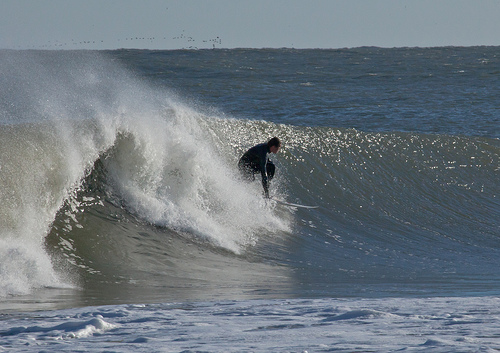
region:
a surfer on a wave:
[224, 122, 289, 205]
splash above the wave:
[5, 37, 213, 183]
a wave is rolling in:
[8, 50, 476, 285]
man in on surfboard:
[230, 125, 319, 217]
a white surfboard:
[256, 189, 320, 213]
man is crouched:
[240, 134, 287, 204]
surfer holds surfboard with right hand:
[222, 120, 325, 225]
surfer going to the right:
[230, 125, 318, 230]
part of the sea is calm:
[159, 42, 488, 117]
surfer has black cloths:
[211, 120, 301, 205]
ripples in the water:
[40, 303, 124, 350]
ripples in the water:
[63, 129, 152, 211]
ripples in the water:
[145, 171, 277, 308]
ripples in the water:
[319, 121, 386, 173]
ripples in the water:
[399, 116, 474, 160]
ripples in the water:
[362, 204, 424, 259]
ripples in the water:
[373, 273, 486, 324]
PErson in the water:
[227, 121, 320, 233]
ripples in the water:
[245, 67, 387, 114]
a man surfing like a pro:
[237, 137, 315, 212]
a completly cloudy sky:
[0, 4, 494, 45]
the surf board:
[264, 192, 320, 210]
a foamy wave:
[3, 76, 249, 292]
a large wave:
[3, 67, 250, 287]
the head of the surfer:
[268, 138, 281, 153]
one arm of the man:
[258, 154, 274, 201]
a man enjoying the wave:
[1, 117, 496, 344]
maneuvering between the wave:
[240, 139, 282, 194]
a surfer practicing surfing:
[235, 133, 317, 213]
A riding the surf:
[231, 119, 323, 236]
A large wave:
[306, 128, 467, 283]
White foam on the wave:
[31, 72, 188, 215]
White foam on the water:
[37, 300, 133, 351]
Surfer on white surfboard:
[270, 187, 325, 219]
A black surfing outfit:
[241, 145, 276, 192]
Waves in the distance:
[297, 39, 461, 76]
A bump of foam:
[323, 295, 399, 332]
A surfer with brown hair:
[263, 123, 283, 158]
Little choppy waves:
[361, 51, 477, 83]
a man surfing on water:
[225, 135, 320, 215]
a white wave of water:
[0, 85, 216, 290]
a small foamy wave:
[60, 315, 120, 340]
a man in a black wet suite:
[234, 143, 284, 210]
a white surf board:
[263, 193, 318, 220]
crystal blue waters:
[211, 46, 482, 108]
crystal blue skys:
[13, 0, 495, 55]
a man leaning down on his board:
[225, 131, 340, 207]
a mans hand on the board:
[250, 170, 275, 205]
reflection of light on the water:
[298, 128, 499, 168]